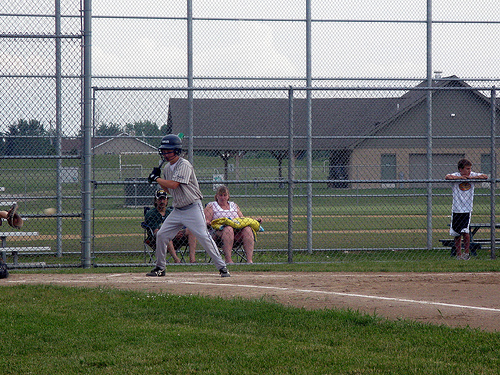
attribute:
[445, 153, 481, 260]
boy — young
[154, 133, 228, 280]
player — looking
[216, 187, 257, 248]
lady — sitting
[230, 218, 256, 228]
blanket — yellow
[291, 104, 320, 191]
fence — chain link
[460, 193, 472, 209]
shirt — white, striped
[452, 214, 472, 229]
shorts — black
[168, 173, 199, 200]
shirt — striped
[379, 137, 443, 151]
building — large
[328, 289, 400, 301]
line — white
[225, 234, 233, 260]
leg — bare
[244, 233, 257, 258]
leg — bare